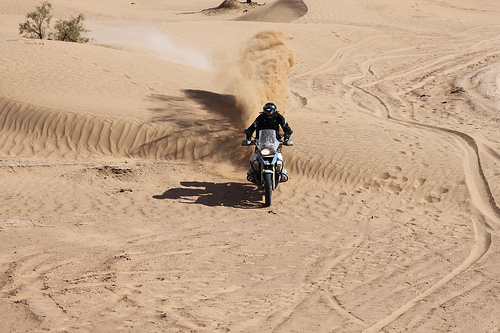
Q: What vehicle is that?
A: Motorcycle.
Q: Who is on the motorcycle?
A: A man.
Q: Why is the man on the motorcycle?
A: Riding.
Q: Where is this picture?
A: Desert.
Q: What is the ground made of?
A: Sand.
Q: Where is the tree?
A: Behind the dune.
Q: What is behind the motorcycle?
A: Dust.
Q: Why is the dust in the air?
A: The motorcycle disturbed it.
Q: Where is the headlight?
A: On front of the motorcycle.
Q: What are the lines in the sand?
A: Tracks.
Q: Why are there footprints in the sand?
A: People have walked in it.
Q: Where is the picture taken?
A: Desert.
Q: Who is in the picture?
A: A man.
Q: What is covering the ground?
A: Sand.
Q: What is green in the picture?
A: Trees.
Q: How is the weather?
A: Sunny.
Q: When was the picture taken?
A: Afternoon.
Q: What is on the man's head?
A: Helmet.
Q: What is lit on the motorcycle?
A: Headlight.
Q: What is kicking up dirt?
A: Motorcycle.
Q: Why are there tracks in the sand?
A: Motorcycle riding.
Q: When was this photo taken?
A: Daytime.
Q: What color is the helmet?
A: Navy blue.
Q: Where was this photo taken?
A: Desert.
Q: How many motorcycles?
A: 1.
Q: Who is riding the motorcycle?
A: Helmet person.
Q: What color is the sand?
A: Tan.